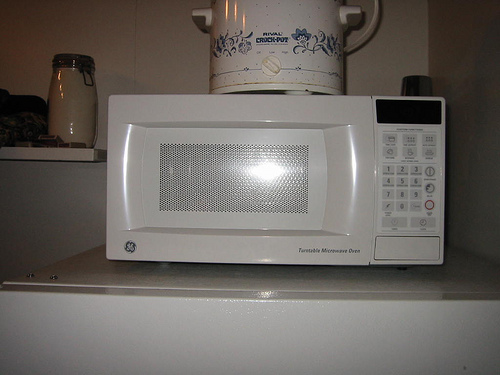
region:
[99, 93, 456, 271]
microwave oven is white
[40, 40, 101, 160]
a jar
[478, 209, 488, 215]
part of a wall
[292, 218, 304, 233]
part of an oven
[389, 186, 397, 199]
part of a button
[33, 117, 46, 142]
part of a shelf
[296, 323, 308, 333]
side of a fridge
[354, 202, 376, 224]
part of a button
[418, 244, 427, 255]
part of a micro wave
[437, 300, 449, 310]
part of a table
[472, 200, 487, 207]
part of a wall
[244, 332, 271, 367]
part of a kitchen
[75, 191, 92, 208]
part of a board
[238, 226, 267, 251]
edge of an oven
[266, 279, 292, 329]
edge of a table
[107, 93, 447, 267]
this is a microwave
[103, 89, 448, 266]
this is a white microwave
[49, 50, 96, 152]
this is a bottle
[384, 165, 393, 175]
this is a number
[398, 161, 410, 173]
this is a number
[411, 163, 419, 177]
this is a number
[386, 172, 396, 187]
this is a number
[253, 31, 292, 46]
this is a word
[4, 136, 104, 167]
this is a counter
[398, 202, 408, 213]
this is a number